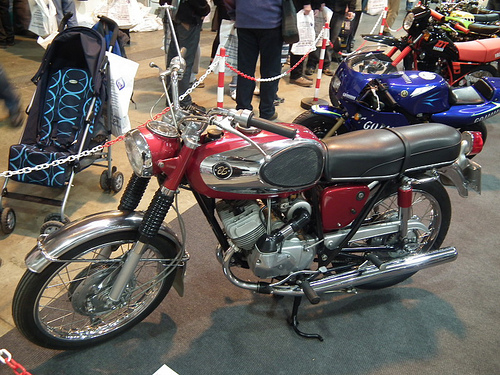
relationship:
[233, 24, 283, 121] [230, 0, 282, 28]
pants and shirt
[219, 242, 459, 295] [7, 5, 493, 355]
exhaust on bike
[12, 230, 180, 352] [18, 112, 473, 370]
front wheel of motorcycle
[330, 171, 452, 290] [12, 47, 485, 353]
wheel of bike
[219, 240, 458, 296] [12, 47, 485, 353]
exhaust on side of bike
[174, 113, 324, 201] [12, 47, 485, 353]
gas tank on bike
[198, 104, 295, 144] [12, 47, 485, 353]
handlebar of bike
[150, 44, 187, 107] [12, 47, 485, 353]
handlebar of bike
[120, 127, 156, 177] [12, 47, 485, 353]
headlight on front of bike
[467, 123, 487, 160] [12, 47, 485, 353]
tail light on bike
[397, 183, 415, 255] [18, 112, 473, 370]
rear shock on motorcycle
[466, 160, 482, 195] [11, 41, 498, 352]
license plate on motorcycle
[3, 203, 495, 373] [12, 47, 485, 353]
carpeting under bike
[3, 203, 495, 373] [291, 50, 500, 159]
carpeting under blue motorcycle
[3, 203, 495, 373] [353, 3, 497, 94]
carpeting under motorcycle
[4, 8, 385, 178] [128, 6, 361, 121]
chain between poles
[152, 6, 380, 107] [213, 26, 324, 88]
people standing on far side of chain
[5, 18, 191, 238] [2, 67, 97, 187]
stroller with circles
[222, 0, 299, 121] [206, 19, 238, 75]
people holding bag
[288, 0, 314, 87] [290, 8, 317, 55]
person holding bag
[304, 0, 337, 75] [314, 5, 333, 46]
person holding bag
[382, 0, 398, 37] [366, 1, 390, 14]
person holding bag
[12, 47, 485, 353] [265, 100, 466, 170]
bike with seat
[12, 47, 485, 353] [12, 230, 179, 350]
bike has front wheel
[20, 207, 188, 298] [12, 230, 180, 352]
silver cover in front wheel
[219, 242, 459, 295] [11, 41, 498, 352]
exhaust on motorcycle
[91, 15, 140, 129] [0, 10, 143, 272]
backpack on stroller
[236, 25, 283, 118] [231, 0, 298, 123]
pants on person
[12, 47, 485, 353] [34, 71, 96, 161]
bike of bags with red or blue writing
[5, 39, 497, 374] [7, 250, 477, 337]
floor under vistors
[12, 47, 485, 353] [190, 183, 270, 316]
bike with a red dt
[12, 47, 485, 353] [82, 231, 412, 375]
bike on display